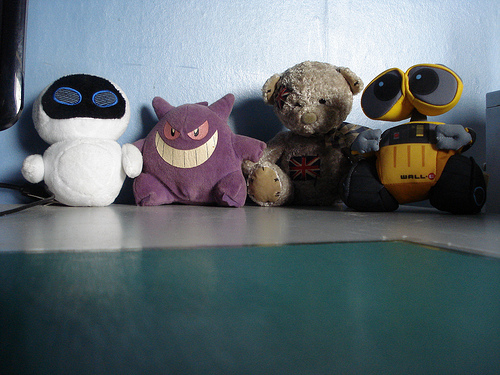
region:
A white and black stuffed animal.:
[20, 71, 143, 206]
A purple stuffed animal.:
[132, 93, 267, 208]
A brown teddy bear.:
[245, 60, 364, 206]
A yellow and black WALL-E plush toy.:
[344, 61, 489, 216]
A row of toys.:
[19, 61, 488, 218]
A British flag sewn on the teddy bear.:
[285, 153, 323, 183]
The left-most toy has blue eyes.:
[91, 89, 118, 108]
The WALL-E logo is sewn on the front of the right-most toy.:
[397, 170, 436, 182]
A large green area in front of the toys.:
[0, 235, 499, 374]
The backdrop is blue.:
[32, 3, 495, 55]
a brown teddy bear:
[256, 67, 361, 217]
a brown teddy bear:
[229, 65, 396, 281]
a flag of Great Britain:
[275, 140, 328, 192]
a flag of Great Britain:
[262, 80, 302, 123]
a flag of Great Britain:
[264, 82, 291, 109]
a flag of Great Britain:
[293, 145, 333, 200]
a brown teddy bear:
[270, 57, 357, 184]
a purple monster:
[146, 94, 239, 199]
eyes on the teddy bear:
[292, 95, 332, 107]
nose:
[299, 108, 319, 125]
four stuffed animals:
[36, 61, 478, 211]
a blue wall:
[121, 8, 290, 71]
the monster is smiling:
[156, 145, 216, 165]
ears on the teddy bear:
[336, 69, 366, 92]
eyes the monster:
[162, 125, 209, 144]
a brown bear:
[274, 81, 350, 130]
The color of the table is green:
[85, 270, 465, 351]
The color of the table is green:
[94, 213, 364, 234]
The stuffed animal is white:
[17, 76, 144, 210]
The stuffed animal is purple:
[131, 90, 267, 215]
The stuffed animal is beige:
[243, 65, 365, 213]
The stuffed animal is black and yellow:
[339, 60, 496, 213]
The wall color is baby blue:
[66, 7, 467, 62]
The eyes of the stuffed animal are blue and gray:
[48, 83, 123, 108]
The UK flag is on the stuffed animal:
[283, 148, 328, 188]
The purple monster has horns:
[147, 80, 240, 118]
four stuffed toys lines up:
[12, 40, 467, 217]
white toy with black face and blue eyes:
[24, 69, 159, 209]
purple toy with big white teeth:
[132, 84, 253, 209]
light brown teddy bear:
[242, 58, 373, 215]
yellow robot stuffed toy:
[350, 55, 475, 207]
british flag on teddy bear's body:
[282, 148, 322, 182]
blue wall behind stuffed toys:
[21, 9, 486, 199]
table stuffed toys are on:
[5, 190, 492, 371]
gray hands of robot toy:
[350, 120, 471, 149]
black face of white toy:
[41, 69, 123, 124]